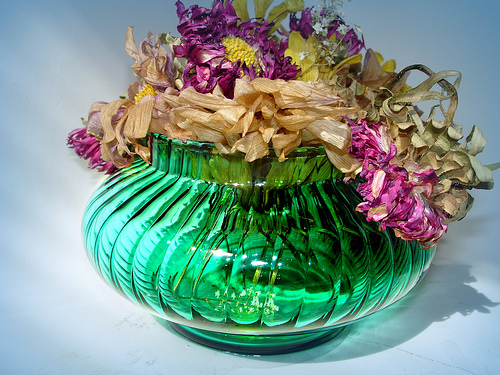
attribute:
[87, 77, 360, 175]
flowers — dead, turning brown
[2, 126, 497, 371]
surface — white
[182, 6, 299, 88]
flowers — purple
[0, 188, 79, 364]
table — light, blue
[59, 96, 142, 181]
flower — wilted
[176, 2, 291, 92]
flower — wilted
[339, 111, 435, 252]
flower — wilted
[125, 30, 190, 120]
flower — wilted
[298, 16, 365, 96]
flower — wilted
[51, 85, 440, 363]
vase — green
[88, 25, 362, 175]
decoration — brown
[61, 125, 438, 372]
vase — green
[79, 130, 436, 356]
pot — beautiful, small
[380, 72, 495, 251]
decoration — brown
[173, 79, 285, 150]
leaves — brown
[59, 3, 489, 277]
decoration — brown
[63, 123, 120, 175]
flower — purple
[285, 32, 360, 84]
flower — yellow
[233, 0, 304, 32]
flower — yellow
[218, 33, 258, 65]
flower — yellow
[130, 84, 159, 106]
flower — yellow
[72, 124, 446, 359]
vase — green, shiny, side, emerald color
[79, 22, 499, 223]
leaves — beige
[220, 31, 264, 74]
flower center — yellow